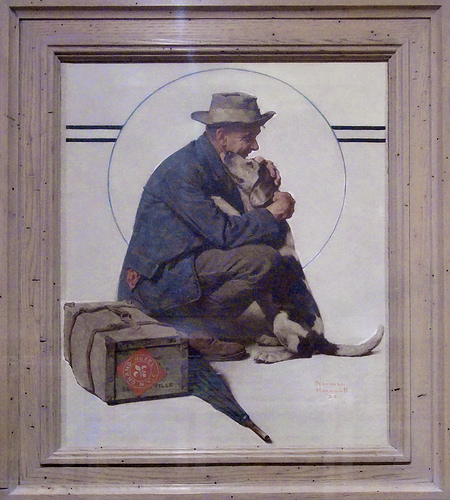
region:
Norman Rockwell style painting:
[65, 63, 386, 446]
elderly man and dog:
[117, 90, 385, 365]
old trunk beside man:
[64, 297, 194, 403]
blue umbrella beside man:
[182, 345, 277, 442]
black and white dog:
[218, 151, 385, 371]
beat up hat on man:
[191, 88, 282, 131]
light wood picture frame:
[2, 0, 445, 498]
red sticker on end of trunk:
[114, 346, 169, 398]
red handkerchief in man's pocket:
[122, 262, 150, 290]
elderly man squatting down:
[115, 89, 278, 362]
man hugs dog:
[128, 89, 336, 314]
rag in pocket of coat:
[102, 168, 173, 314]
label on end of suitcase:
[69, 276, 195, 411]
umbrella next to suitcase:
[84, 269, 299, 438]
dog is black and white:
[190, 148, 339, 358]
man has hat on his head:
[181, 86, 299, 178]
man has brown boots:
[181, 87, 314, 369]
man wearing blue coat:
[119, 115, 351, 345]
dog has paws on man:
[197, 121, 327, 243]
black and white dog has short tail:
[179, 110, 387, 366]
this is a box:
[74, 306, 179, 393]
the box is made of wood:
[58, 297, 175, 397]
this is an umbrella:
[190, 360, 269, 442]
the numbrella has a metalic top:
[243, 416, 272, 441]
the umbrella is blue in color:
[190, 357, 245, 424]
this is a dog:
[221, 150, 306, 355]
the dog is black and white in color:
[219, 148, 301, 359]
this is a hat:
[193, 91, 271, 123]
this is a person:
[100, 98, 263, 353]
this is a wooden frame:
[0, 0, 441, 491]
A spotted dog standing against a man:
[219, 148, 386, 358]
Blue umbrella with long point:
[184, 352, 274, 449]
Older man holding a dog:
[114, 86, 340, 367]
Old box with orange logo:
[64, 295, 205, 416]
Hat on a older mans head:
[193, 83, 297, 169]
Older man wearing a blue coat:
[121, 91, 283, 375]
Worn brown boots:
[182, 310, 262, 364]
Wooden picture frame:
[5, 1, 447, 497]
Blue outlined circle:
[91, 63, 357, 257]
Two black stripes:
[60, 109, 397, 154]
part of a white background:
[301, 390, 359, 427]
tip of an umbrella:
[245, 421, 274, 446]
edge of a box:
[183, 337, 191, 384]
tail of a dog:
[335, 333, 380, 367]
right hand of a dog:
[278, 191, 292, 219]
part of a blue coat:
[168, 172, 202, 208]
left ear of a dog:
[255, 169, 270, 196]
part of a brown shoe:
[222, 335, 247, 360]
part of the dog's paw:
[252, 347, 280, 371]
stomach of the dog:
[276, 268, 305, 309]